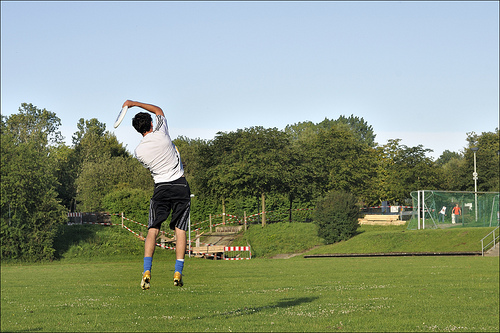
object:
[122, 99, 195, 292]
boy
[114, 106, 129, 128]
frisbee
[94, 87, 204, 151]
air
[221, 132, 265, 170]
green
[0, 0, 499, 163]
sky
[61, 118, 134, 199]
trees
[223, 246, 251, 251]
white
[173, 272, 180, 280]
orange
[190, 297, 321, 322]
shadow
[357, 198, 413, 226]
large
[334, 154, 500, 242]
area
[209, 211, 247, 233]
railing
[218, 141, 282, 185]
thick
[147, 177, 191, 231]
short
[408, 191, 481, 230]
net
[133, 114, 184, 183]
shirt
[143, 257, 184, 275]
socks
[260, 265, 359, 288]
grass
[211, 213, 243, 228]
ribbons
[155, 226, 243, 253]
bridge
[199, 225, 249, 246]
background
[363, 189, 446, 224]
distance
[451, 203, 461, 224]
people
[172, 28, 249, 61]
clear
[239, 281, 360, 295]
patch